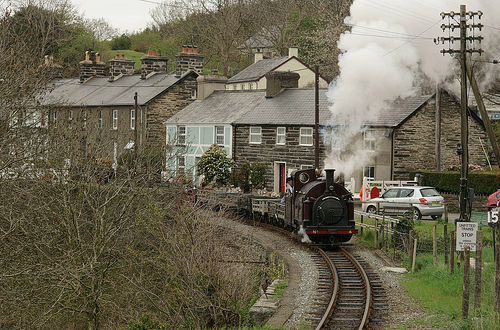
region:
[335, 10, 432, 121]
Thick white smoke billowing from the train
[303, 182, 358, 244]
A small black train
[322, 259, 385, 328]
Wooden train tracks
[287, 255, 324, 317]
Small rocks by the train tracks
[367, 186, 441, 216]
A grey van behind the train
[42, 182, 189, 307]
Dead shrubbery by the train tracks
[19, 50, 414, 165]
Buildings behind the train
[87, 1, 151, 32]
A cloudy sky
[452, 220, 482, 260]
A sign warning people to stop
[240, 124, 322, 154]
Three windows on the building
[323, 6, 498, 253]
Smoke is coming from the train.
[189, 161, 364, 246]
The train is moving.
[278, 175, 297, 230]
Someone is standing on the train.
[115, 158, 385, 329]
The train is on the tracks.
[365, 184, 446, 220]
The car is silver.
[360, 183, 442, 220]
The car is parked.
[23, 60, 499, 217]
The houses are next to the track.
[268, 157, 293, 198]
The door is red.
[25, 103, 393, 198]
Many windows are on the side of the buildings.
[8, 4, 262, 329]
The trees are bare.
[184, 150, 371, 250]
a train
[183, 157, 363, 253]
a small train on a track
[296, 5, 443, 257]
a cloud of steam comes out of the train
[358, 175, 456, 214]
a car is parked in front of a white fence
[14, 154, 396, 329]
the train tracks run alongside a building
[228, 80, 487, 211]
a grey brick building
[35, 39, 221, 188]
the building to the far left has four fireplaces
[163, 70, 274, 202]
the middle building is light blue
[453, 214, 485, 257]
a white sign by the tracks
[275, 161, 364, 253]
a person sits on the train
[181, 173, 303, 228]
the cars are open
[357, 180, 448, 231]
the car is silver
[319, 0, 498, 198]
the steam is rising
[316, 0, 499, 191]
the steam is white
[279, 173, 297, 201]
the engineer is on the train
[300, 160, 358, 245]
the front of the train is black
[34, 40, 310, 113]
the houses have many chimneys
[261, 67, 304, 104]
this is a chimney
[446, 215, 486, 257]
this is a white sign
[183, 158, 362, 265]
this is a train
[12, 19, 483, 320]
steam engine train driving through a neighborhood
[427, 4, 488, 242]
electric telephone pole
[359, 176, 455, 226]
silver car waiting for the train to pass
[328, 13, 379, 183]
steam coming from train engine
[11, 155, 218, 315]
thick tree branches with no leaves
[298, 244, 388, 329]
slightly curved train tracks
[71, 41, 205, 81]
row of brick chimneys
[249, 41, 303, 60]
two white chimneys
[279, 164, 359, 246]
black front car of train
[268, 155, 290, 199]
red door to a house